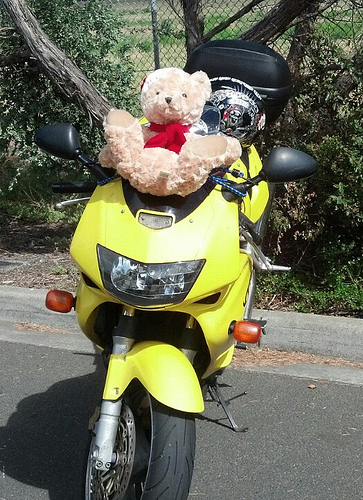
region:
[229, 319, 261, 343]
motorcycle turn signal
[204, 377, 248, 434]
metal motorcycle kickstand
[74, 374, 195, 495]
motorcycle front tire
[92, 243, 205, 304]
motorcycle main headlight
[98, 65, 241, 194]
light brown teddy bear with red ribbon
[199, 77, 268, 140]
motorcycle helmet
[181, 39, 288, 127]
rear-mounted motorcycle storage caddy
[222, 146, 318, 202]
motorcycle rear view mirror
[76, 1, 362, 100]
silver metal chainlink fence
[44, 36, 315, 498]
teddy bear attached to motorcycle windshield with bungee cords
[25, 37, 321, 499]
teddy bear on a yellow motorcycle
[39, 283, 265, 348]
orange lights on the side of a motorcycle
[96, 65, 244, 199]
beige teddy bear with a red bow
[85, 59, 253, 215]
teddy bear is attached by bungee cords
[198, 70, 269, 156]
a decorated crash helmet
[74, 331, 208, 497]
front wheel of a motorcycle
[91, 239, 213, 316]
headlamp on a yellow motorcycle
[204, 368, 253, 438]
kickstand of a motorcycle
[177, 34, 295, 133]
black storage box on the back of a motorcycle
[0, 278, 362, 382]
concrete curb next to a road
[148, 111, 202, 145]
red bow on bear's neck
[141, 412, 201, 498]
black tire on motorcycle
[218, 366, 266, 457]
black kickstand on side of motorcycle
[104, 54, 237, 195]
light brown teddy bear on motorcycle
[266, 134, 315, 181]
black mirror on motorcycle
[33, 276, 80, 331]
orange brake light on bike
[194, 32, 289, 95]
black closed box on bike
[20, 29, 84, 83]
shredded grey tree trunk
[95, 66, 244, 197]
a large brown teddy bear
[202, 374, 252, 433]
a metal kick stand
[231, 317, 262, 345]
a bright orange reflector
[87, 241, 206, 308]
a large headlamp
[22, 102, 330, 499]
a bright yellow motorcycle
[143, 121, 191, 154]
a bright red bow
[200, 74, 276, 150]
a motorcycle covered in graphics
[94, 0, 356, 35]
a chain link fence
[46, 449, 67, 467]
par tof a dsahde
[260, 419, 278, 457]
par tof a road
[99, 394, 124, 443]
par tof a metal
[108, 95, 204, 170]
brown teddy bear in a motorcycle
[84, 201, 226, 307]
yellow motrocycle in the pavement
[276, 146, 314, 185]
right mirror of the motorcycle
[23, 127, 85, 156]
left mirror in the motorcycle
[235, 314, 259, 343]
signal red light right side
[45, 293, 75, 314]
red signal light lef side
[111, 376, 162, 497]
black wheel of the motorcycle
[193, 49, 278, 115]
black box in the motrocycle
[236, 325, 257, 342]
the light is orange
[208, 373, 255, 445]
the kickstand is down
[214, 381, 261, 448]
the kickstand is gray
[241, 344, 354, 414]
leaves are on the ground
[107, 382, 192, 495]
the wheel is black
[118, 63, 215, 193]
bear is on the bike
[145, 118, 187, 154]
the scarf is on the bear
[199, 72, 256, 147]
helmet is on the bike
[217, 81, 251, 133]
designs are on the helmet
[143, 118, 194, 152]
the scarf is red